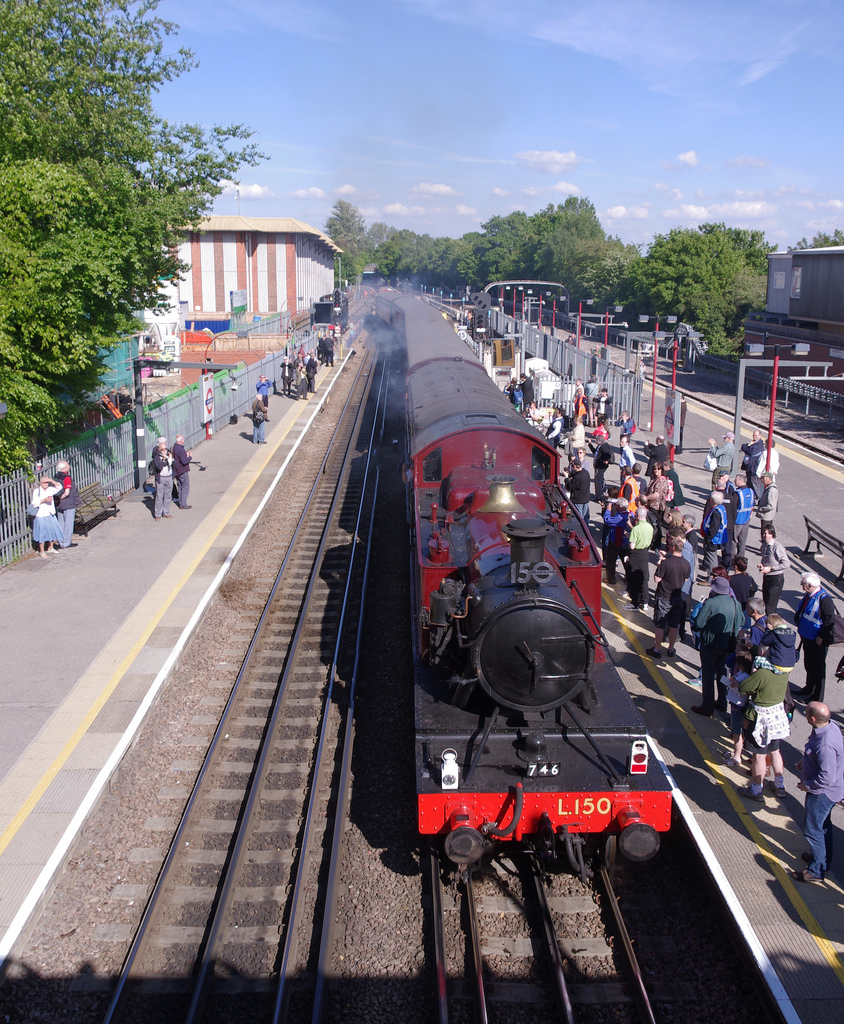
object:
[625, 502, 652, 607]
person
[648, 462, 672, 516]
person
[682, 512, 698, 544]
person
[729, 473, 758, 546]
person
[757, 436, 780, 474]
person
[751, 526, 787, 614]
person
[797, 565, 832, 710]
people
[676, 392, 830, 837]
platform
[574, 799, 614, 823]
number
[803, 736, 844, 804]
shirt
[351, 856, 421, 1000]
gravel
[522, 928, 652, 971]
tracks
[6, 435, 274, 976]
line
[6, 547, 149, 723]
platform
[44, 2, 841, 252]
sky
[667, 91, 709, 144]
cloud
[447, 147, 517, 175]
cloud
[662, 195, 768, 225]
cloud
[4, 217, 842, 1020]
station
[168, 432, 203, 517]
person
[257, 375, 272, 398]
person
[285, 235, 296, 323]
stripes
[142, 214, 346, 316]
building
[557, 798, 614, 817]
writing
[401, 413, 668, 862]
engine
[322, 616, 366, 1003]
tracks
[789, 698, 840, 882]
man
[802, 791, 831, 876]
jeans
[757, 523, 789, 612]
people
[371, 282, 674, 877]
train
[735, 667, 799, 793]
person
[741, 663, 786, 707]
shirt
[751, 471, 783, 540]
person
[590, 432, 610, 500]
person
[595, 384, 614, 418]
person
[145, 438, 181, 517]
person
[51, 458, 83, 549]
person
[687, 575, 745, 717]
person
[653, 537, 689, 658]
person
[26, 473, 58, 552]
person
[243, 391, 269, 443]
person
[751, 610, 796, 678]
person